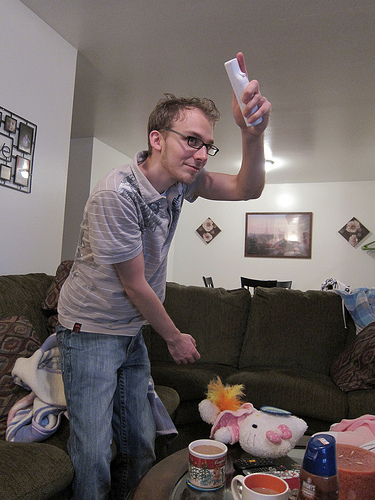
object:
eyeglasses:
[153, 122, 219, 158]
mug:
[184, 434, 230, 491]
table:
[133, 432, 370, 499]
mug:
[229, 469, 289, 499]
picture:
[0, 105, 38, 196]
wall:
[4, 2, 78, 276]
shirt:
[56, 149, 211, 337]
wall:
[170, 182, 372, 295]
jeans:
[55, 321, 157, 499]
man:
[57, 44, 271, 497]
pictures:
[190, 204, 367, 262]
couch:
[148, 280, 373, 433]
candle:
[333, 442, 375, 498]